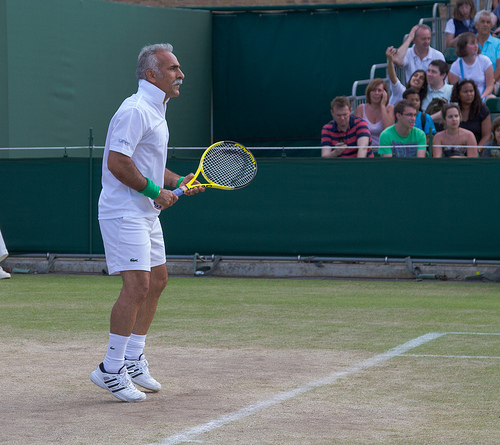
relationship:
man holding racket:
[89, 41, 260, 403] [162, 139, 257, 201]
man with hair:
[89, 41, 208, 402] [135, 41, 172, 82]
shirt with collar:
[107, 91, 170, 201] [136, 75, 173, 109]